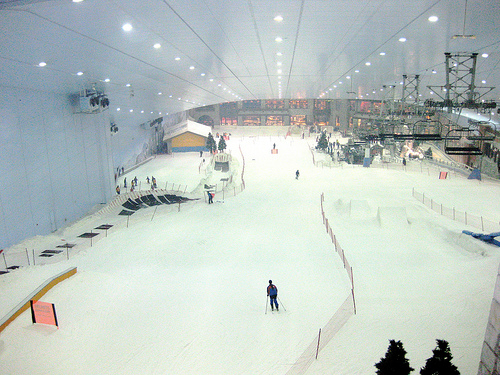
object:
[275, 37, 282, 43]
light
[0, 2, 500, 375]
dome stadium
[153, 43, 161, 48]
dome/stadium light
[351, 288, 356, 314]
red fence-part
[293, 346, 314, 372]
red fence-part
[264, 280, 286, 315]
skiier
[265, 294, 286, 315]
2 poles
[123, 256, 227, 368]
white snow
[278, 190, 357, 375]
fence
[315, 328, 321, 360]
pole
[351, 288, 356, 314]
pole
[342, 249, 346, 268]
pole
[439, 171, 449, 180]
object